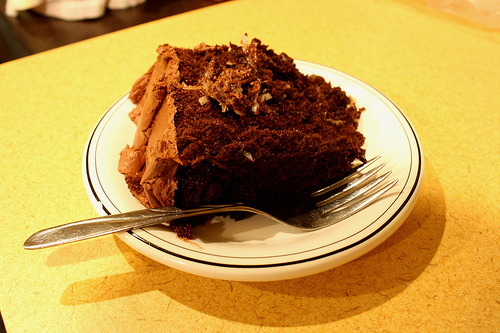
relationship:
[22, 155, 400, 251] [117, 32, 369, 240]
fork next to cake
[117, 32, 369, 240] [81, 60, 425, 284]
cake served on plate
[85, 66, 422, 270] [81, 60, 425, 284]
ring around plate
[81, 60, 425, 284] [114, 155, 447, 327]
plate casts shadow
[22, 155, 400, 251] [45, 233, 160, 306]
fork casts shadow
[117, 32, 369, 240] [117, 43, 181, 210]
cake topped with frosting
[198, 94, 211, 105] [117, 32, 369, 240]
piece inside cake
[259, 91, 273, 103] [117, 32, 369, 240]
piece inside cake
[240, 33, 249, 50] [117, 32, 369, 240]
piece inside cake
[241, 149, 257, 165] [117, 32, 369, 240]
piece inside cake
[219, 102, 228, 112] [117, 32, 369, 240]
piece inside cake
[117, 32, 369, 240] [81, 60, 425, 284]
cake sitting on plate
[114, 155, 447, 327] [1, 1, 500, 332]
shadow cast on table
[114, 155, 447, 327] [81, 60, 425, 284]
shadow of plate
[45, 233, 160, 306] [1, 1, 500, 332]
shadow cast on table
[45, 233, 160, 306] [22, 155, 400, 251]
shadow of fork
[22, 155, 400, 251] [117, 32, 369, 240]
fork sitting next to cake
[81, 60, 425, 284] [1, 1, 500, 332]
plate sitting on table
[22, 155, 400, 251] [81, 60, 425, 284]
fork resting on plate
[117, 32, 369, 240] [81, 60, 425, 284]
cake on top of plate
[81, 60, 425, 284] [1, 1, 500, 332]
plate on top of table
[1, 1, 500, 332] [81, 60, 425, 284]
table underneath plate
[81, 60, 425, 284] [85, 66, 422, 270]
plate has ring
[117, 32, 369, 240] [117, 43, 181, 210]
cake covered with frosting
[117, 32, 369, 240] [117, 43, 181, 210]
cake has frosting